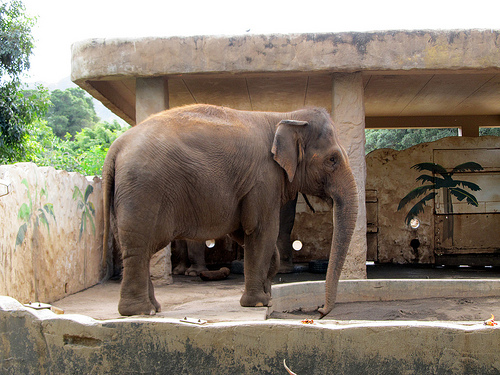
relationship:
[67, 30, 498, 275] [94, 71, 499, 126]
shelter has ceiling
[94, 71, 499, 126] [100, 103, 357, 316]
ceiling over elephant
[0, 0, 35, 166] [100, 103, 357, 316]
tree behind elephant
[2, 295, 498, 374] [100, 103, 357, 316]
wall in front of elephant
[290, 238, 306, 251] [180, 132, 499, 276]
hole in wall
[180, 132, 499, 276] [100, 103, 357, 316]
wall behind elephant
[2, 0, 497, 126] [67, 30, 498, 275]
sky above shelter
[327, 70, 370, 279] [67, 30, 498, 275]
column supporting shelter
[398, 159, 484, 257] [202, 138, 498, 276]
tree painted on wall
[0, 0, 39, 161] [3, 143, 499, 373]
tree outside enclosure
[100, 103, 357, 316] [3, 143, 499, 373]
elephant in enclosure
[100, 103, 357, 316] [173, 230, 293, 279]
elephant has legs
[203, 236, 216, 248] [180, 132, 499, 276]
hole in wall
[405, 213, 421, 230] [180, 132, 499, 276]
hole in wall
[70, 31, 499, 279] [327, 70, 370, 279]
structure has column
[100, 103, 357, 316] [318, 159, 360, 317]
elephant has trunk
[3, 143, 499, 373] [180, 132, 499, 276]
enclosure has wall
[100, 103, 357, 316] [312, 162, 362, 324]
elephant has trunk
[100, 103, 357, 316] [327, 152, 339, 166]
elephant has eye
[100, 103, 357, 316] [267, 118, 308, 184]
elephant has ear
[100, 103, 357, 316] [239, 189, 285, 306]
elephant has leg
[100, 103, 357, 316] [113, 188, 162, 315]
elephant has leg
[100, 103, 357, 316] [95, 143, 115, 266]
elephant has tail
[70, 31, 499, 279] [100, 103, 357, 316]
structure near elephant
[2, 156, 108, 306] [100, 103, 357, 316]
wall near elephant